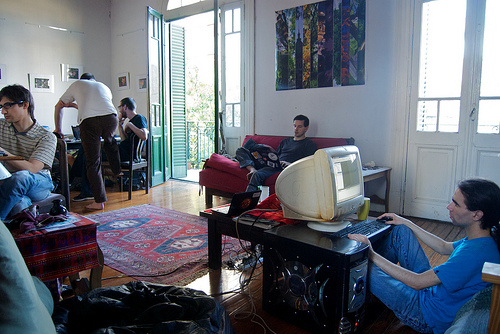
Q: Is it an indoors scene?
A: Yes, it is indoors.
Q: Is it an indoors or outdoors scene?
A: It is indoors.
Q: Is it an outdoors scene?
A: No, it is indoors.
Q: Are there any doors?
A: Yes, there is a door.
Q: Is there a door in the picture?
A: Yes, there is a door.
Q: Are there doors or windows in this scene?
A: Yes, there is a door.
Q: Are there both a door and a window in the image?
A: Yes, there are both a door and a window.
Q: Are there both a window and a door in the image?
A: Yes, there are both a door and a window.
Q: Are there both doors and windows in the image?
A: Yes, there are both a door and a window.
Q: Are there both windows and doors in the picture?
A: Yes, there are both a door and a window.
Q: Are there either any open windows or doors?
A: Yes, there is an open door.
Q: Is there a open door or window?
A: Yes, there is an open door.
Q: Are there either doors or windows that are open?
A: Yes, the door is open.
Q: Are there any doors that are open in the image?
A: Yes, there is an open door.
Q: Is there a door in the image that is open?
A: Yes, there is a door that is open.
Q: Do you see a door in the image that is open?
A: Yes, there is a door that is open.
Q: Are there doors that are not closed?
A: Yes, there is a open door.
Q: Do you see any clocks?
A: No, there are no clocks.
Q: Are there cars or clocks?
A: No, there are no clocks or cars.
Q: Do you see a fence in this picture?
A: No, there are no fences.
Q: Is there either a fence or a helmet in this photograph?
A: No, there are no fences or helmets.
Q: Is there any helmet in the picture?
A: No, there are no helmets.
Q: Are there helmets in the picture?
A: No, there are no helmets.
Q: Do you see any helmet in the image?
A: No, there are no helmets.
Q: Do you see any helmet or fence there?
A: No, there are no helmets or fences.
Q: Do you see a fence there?
A: No, there are no fences.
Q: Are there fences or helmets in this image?
A: No, there are no fences or helmets.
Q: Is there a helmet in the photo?
A: No, there are no helmets.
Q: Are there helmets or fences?
A: No, there are no helmets or fences.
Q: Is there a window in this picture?
A: Yes, there is a window.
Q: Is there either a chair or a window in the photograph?
A: Yes, there is a window.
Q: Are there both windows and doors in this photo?
A: Yes, there are both a window and a door.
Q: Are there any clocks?
A: No, there are no clocks.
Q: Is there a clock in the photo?
A: No, there are no clocks.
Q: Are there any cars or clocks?
A: No, there are no clocks or cars.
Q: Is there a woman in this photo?
A: No, there are no women.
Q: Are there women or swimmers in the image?
A: No, there are no women or swimmers.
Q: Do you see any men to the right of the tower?
A: Yes, there is a man to the right of the tower.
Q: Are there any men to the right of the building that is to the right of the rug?
A: Yes, there is a man to the right of the tower.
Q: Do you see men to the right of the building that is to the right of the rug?
A: Yes, there is a man to the right of the tower.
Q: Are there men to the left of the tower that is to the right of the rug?
A: No, the man is to the right of the tower.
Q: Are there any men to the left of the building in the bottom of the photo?
A: No, the man is to the right of the tower.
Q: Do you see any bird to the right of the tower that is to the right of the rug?
A: No, there is a man to the right of the tower.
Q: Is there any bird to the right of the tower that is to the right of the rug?
A: No, there is a man to the right of the tower.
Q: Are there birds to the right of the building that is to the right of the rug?
A: No, there is a man to the right of the tower.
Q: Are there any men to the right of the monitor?
A: Yes, there is a man to the right of the monitor.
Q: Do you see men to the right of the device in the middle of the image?
A: Yes, there is a man to the right of the monitor.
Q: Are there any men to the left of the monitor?
A: No, the man is to the right of the monitor.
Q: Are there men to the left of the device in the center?
A: No, the man is to the right of the monitor.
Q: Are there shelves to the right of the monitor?
A: No, there is a man to the right of the monitor.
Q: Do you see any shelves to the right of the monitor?
A: No, there is a man to the right of the monitor.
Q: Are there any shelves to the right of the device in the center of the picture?
A: No, there is a man to the right of the monitor.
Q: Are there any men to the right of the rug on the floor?
A: Yes, there is a man to the right of the rug.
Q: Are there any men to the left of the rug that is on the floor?
A: No, the man is to the right of the rug.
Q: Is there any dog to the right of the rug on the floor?
A: No, there is a man to the right of the rug.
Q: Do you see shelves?
A: No, there are no shelves.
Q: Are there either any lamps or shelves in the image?
A: No, there are no shelves or lamps.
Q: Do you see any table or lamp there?
A: Yes, there is a table.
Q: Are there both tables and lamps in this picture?
A: No, there is a table but no lamps.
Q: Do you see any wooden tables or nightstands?
A: Yes, there is a wood table.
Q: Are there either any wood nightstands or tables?
A: Yes, there is a wood table.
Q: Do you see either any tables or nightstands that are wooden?
A: Yes, the table is wooden.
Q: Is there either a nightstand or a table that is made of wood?
A: Yes, the table is made of wood.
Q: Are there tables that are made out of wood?
A: Yes, there is a table that is made of wood.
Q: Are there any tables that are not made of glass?
A: Yes, there is a table that is made of wood.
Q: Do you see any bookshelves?
A: No, there are no bookshelves.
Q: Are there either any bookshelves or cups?
A: No, there are no bookshelves or cups.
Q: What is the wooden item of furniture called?
A: The piece of furniture is a table.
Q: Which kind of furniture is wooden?
A: The furniture is a table.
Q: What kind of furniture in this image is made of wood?
A: The furniture is a table.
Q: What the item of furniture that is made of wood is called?
A: The piece of furniture is a table.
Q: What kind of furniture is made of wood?
A: The furniture is a table.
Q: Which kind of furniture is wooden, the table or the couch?
A: The table is wooden.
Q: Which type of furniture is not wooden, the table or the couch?
A: The couch is not wooden.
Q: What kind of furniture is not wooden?
A: The furniture is a couch.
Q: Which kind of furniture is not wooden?
A: The furniture is a couch.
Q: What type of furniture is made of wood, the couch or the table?
A: The table is made of wood.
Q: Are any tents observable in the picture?
A: No, there are no tents.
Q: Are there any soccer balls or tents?
A: No, there are no tents or soccer balls.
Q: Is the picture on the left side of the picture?
A: Yes, the picture is on the left of the image.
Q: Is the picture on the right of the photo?
A: No, the picture is on the left of the image.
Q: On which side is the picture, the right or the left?
A: The picture is on the left of the image.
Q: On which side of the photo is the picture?
A: The picture is on the left of the image.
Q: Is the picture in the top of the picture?
A: Yes, the picture is in the top of the image.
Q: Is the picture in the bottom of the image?
A: No, the picture is in the top of the image.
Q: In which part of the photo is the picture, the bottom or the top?
A: The picture is in the top of the image.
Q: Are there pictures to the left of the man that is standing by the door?
A: Yes, there is a picture to the left of the man.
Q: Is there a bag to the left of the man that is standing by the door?
A: No, there is a picture to the left of the man.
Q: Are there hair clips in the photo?
A: No, there are no hair clips.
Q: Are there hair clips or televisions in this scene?
A: No, there are no hair clips or televisions.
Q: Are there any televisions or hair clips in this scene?
A: No, there are no hair clips or televisions.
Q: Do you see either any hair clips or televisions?
A: No, there are no hair clips or televisions.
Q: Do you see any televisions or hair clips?
A: No, there are no hair clips or televisions.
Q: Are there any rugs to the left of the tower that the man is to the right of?
A: Yes, there is a rug to the left of the tower.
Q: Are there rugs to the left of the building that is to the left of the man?
A: Yes, there is a rug to the left of the tower.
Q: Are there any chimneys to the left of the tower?
A: No, there is a rug to the left of the tower.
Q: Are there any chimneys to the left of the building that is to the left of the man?
A: No, there is a rug to the left of the tower.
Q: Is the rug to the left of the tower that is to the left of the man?
A: Yes, the rug is to the left of the tower.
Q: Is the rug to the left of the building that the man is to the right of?
A: Yes, the rug is to the left of the tower.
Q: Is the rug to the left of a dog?
A: No, the rug is to the left of the tower.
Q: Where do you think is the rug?
A: The rug is on the floor.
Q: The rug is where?
A: The rug is on the floor.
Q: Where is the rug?
A: The rug is on the floor.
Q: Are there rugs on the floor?
A: Yes, there is a rug on the floor.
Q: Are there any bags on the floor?
A: No, there is a rug on the floor.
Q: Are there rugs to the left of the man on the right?
A: Yes, there is a rug to the left of the man.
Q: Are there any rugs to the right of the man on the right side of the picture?
A: No, the rug is to the left of the man.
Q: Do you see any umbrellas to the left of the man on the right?
A: No, there is a rug to the left of the man.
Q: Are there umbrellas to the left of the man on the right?
A: No, there is a rug to the left of the man.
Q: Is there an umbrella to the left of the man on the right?
A: No, there is a rug to the left of the man.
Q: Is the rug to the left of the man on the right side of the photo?
A: Yes, the rug is to the left of the man.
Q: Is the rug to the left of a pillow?
A: No, the rug is to the left of the man.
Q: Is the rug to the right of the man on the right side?
A: No, the rug is to the left of the man.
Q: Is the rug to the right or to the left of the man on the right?
A: The rug is to the left of the man.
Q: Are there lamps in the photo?
A: No, there are no lamps.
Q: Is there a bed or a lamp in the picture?
A: No, there are no lamps or beds.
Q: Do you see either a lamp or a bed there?
A: No, there are no lamps or beds.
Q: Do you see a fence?
A: No, there are no fences.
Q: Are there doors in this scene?
A: Yes, there is a door.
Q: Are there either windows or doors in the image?
A: Yes, there is a door.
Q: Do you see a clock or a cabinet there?
A: No, there are no clocks or cabinets.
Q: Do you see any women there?
A: No, there are no women.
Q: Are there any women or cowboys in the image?
A: No, there are no women or cowboys.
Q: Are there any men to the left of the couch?
A: Yes, there is a man to the left of the couch.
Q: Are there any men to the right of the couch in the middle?
A: No, the man is to the left of the couch.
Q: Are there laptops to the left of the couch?
A: No, there is a man to the left of the couch.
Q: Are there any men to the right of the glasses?
A: Yes, there is a man to the right of the glasses.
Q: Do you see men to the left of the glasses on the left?
A: No, the man is to the right of the glasses.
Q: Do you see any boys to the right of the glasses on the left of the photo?
A: No, there is a man to the right of the glasses.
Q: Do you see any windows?
A: Yes, there is a window.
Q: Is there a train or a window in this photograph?
A: Yes, there is a window.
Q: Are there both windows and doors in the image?
A: Yes, there are both a window and a door.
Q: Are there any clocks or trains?
A: No, there are no clocks or trains.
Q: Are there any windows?
A: Yes, there are windows.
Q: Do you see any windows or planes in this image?
A: Yes, there are windows.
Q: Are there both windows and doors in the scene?
A: Yes, there are both windows and doors.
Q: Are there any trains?
A: No, there are no trains.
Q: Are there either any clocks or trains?
A: No, there are no trains or clocks.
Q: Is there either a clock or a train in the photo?
A: No, there are no trains or clocks.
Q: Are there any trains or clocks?
A: No, there are no trains or clocks.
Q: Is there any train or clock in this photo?
A: No, there are no trains or clocks.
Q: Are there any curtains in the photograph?
A: No, there are no curtains.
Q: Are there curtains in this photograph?
A: No, there are no curtains.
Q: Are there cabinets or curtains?
A: No, there are no curtains or cabinets.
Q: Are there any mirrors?
A: No, there are no mirrors.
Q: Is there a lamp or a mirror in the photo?
A: No, there are no mirrors or lamps.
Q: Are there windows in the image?
A: Yes, there is a window.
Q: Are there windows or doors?
A: Yes, there is a window.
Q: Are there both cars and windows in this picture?
A: No, there is a window but no cars.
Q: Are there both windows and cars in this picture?
A: No, there is a window but no cars.